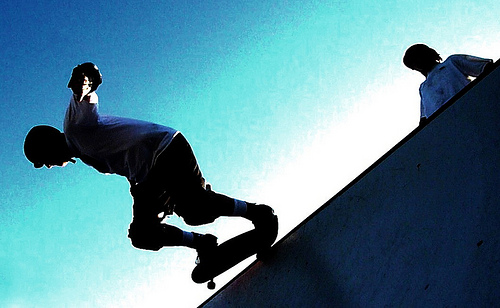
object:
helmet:
[23, 124, 65, 170]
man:
[24, 62, 277, 267]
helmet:
[15, 111, 65, 173]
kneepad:
[126, 222, 168, 252]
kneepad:
[178, 184, 218, 226]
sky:
[3, 0, 406, 121]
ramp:
[206, 87, 497, 307]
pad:
[66, 61, 103, 102]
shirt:
[418, 53, 494, 119]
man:
[402, 42, 497, 126]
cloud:
[0, 0, 499, 308]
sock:
[234, 199, 248, 217]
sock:
[181, 231, 194, 245]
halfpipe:
[198, 58, 497, 306]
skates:
[188, 231, 220, 265]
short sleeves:
[62, 91, 99, 132]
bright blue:
[267, 45, 348, 120]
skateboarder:
[28, 46, 314, 286]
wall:
[267, 97, 499, 307]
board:
[191, 214, 280, 289]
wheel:
[207, 282, 216, 290]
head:
[21, 124, 71, 169]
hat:
[402, 44, 442, 70]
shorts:
[126, 133, 218, 251]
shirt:
[63, 92, 182, 187]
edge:
[197, 58, 494, 305]